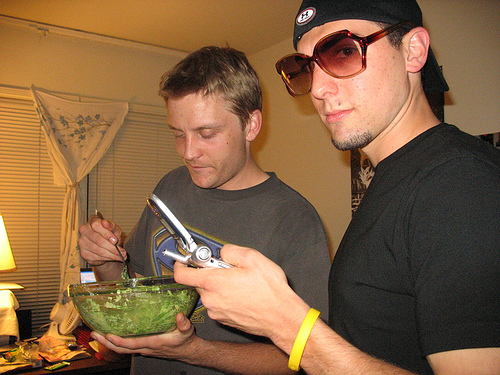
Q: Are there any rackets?
A: No, there are no rackets.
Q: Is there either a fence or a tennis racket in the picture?
A: No, there are no rackets or fences.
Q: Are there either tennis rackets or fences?
A: No, there are no tennis rackets or fences.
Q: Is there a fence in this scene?
A: No, there are no fences.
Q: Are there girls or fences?
A: No, there are no fences or girls.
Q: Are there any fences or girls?
A: No, there are no fences or girls.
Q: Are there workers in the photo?
A: No, there are no workers.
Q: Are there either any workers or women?
A: No, there are no workers or women.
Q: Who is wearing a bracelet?
A: The man is wearing a bracelet.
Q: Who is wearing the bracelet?
A: The man is wearing a bracelet.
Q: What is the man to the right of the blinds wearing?
A: The man is wearing a bracelet.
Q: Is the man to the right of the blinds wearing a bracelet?
A: Yes, the man is wearing a bracelet.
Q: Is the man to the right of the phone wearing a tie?
A: No, the man is wearing a bracelet.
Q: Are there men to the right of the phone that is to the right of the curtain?
A: Yes, there is a man to the right of the telephone.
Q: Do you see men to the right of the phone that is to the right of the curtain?
A: Yes, there is a man to the right of the telephone.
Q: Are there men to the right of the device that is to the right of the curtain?
A: Yes, there is a man to the right of the telephone.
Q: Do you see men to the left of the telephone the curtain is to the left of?
A: No, the man is to the right of the telephone.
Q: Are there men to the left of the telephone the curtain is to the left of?
A: No, the man is to the right of the telephone.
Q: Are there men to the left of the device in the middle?
A: No, the man is to the right of the telephone.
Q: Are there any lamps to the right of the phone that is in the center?
A: No, there is a man to the right of the telephone.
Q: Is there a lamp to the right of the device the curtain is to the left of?
A: No, there is a man to the right of the telephone.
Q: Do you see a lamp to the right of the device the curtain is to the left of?
A: No, there is a man to the right of the telephone.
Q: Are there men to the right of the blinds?
A: Yes, there is a man to the right of the blinds.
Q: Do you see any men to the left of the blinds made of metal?
A: No, the man is to the right of the blinds.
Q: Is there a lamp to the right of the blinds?
A: No, there is a man to the right of the blinds.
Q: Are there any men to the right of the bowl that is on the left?
A: Yes, there is a man to the right of the bowl.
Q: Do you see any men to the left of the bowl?
A: No, the man is to the right of the bowl.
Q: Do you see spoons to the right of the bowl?
A: No, there is a man to the right of the bowl.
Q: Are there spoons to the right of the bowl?
A: No, there is a man to the right of the bowl.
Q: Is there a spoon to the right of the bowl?
A: No, there is a man to the right of the bowl.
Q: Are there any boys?
A: No, there are no boys.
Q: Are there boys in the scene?
A: No, there are no boys.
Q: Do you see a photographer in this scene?
A: No, there are no photographers.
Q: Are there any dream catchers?
A: No, there are no dream catchers.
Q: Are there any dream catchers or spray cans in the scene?
A: No, there are no dream catchers or spray cans.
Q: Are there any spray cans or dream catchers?
A: No, there are no dream catchers or spray cans.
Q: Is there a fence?
A: No, there are no fences.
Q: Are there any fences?
A: No, there are no fences.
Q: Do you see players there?
A: No, there are no players.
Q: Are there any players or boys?
A: No, there are no players or boys.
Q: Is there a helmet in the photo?
A: No, there are no helmets.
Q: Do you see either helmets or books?
A: No, there are no helmets or books.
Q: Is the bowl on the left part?
A: Yes, the bowl is on the left of the image.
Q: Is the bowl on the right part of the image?
A: No, the bowl is on the left of the image.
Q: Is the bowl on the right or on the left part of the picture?
A: The bowl is on the left of the image.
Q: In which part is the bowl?
A: The bowl is on the left of the image.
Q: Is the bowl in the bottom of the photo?
A: Yes, the bowl is in the bottom of the image.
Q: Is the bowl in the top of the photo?
A: No, the bowl is in the bottom of the image.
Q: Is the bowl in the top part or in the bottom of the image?
A: The bowl is in the bottom of the image.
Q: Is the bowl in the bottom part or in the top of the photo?
A: The bowl is in the bottom of the image.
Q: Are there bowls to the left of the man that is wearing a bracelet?
A: Yes, there is a bowl to the left of the man.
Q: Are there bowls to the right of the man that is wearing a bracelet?
A: No, the bowl is to the left of the man.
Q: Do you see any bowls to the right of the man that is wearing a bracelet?
A: No, the bowl is to the left of the man.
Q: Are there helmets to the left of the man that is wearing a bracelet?
A: No, there is a bowl to the left of the man.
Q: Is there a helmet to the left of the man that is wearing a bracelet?
A: No, there is a bowl to the left of the man.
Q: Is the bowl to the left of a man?
A: Yes, the bowl is to the left of a man.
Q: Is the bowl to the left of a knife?
A: No, the bowl is to the left of a man.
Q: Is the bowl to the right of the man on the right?
A: No, the bowl is to the left of the man.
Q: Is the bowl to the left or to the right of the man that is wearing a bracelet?
A: The bowl is to the left of the man.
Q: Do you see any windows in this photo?
A: Yes, there are windows.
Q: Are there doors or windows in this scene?
A: Yes, there are windows.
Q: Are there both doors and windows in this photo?
A: No, there are windows but no doors.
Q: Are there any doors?
A: No, there are no doors.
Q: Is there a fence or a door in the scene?
A: No, there are no doors or fences.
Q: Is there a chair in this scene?
A: No, there are no chairs.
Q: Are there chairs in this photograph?
A: No, there are no chairs.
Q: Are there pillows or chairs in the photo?
A: No, there are no chairs or pillows.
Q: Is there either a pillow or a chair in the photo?
A: No, there are no chairs or pillows.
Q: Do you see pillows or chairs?
A: No, there are no chairs or pillows.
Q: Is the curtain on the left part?
A: Yes, the curtain is on the left of the image.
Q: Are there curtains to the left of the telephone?
A: Yes, there is a curtain to the left of the telephone.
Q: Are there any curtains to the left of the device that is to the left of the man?
A: Yes, there is a curtain to the left of the telephone.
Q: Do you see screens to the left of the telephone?
A: No, there is a curtain to the left of the telephone.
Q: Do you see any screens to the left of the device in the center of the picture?
A: No, there is a curtain to the left of the telephone.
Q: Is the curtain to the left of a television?
A: No, the curtain is to the left of the phone.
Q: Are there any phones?
A: Yes, there is a phone.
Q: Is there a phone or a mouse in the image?
A: Yes, there is a phone.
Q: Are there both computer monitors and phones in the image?
A: No, there is a phone but no computer monitors.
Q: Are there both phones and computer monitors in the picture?
A: No, there is a phone but no computer monitors.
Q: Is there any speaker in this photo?
A: No, there are no speakers.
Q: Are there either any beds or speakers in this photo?
A: No, there are no speakers or beds.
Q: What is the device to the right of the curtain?
A: The device is a phone.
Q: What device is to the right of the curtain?
A: The device is a phone.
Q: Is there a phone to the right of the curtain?
A: Yes, there is a phone to the right of the curtain.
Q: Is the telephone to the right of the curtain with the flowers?
A: Yes, the telephone is to the right of the curtain.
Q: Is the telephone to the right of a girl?
A: No, the telephone is to the right of the curtain.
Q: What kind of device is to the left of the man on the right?
A: The device is a phone.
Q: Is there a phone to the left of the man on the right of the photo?
A: Yes, there is a phone to the left of the man.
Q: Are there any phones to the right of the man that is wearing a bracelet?
A: No, the phone is to the left of the man.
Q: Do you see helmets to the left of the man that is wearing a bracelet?
A: No, there is a phone to the left of the man.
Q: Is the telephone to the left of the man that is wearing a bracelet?
A: Yes, the telephone is to the left of the man.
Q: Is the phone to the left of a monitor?
A: No, the phone is to the left of the man.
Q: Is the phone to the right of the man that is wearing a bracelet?
A: No, the phone is to the left of the man.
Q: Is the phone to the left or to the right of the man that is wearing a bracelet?
A: The phone is to the left of the man.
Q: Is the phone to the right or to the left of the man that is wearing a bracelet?
A: The phone is to the left of the man.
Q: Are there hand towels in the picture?
A: No, there are no hand towels.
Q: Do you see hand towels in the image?
A: No, there are no hand towels.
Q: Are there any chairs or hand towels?
A: No, there are no hand towels or chairs.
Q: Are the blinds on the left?
A: Yes, the blinds are on the left of the image.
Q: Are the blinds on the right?
A: No, the blinds are on the left of the image.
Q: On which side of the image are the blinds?
A: The blinds are on the left of the image.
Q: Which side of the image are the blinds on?
A: The blinds are on the left of the image.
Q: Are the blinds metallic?
A: Yes, the blinds are metallic.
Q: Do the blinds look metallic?
A: Yes, the blinds are metallic.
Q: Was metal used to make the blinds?
A: Yes, the blinds are made of metal.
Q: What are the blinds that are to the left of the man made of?
A: The blinds are made of metal.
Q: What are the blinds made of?
A: The blinds are made of metal.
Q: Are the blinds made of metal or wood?
A: The blinds are made of metal.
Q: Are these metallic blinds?
A: Yes, these are metallic blinds.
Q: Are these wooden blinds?
A: No, these are metallic blinds.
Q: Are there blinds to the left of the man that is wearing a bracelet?
A: Yes, there are blinds to the left of the man.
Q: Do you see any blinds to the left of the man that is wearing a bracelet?
A: Yes, there are blinds to the left of the man.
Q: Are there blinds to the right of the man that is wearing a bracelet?
A: No, the blinds are to the left of the man.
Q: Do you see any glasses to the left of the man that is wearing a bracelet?
A: No, there are blinds to the left of the man.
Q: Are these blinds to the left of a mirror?
A: No, the blinds are to the left of the man.